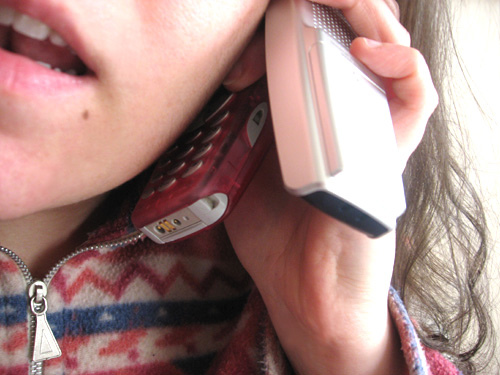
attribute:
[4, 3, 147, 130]
teeth — white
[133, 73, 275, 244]
case — pink 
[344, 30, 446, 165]
finger — pinkie